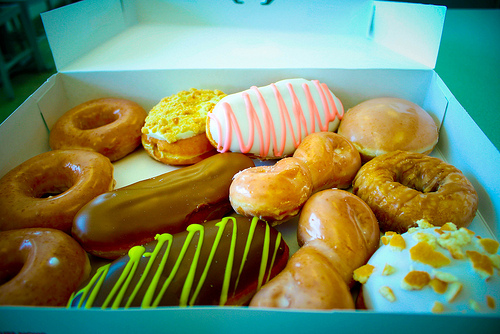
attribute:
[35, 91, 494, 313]
donuts — delicious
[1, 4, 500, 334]
box — green, white, open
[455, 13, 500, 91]
table — gray, green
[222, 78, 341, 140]
donut — vanilla, filled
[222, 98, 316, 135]
glaze — pink, white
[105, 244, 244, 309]
glaze — brown, yellow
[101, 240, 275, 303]
donut — filled, chocolate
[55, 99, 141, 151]
donut — glazed, round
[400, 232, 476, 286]
topping — yellow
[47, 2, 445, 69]
lid — white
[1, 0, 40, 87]
cart — gray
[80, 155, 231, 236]
donut — brown, long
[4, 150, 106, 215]
donut — round, glazed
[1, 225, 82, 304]
donut — glazed, round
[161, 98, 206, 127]
topping — white, yellow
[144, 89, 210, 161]
donut — round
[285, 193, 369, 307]
donut — long, glazed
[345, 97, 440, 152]
donut — round, jelly filled, glazed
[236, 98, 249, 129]
frosting — vanilla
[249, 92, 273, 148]
stripes — pink, orange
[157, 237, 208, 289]
stripes — yellow, green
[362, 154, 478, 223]
donut — cake, glazed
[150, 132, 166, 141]
glaze — white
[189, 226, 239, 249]
topping — green